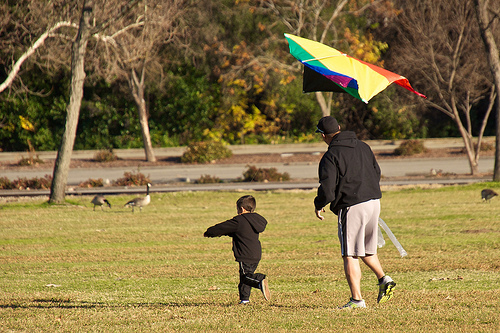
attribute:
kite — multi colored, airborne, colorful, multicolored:
[281, 25, 433, 109]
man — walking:
[315, 113, 404, 309]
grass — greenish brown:
[3, 184, 500, 331]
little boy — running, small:
[201, 186, 278, 306]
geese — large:
[89, 182, 153, 210]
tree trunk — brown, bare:
[45, 4, 110, 205]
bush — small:
[184, 136, 239, 160]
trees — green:
[3, 2, 500, 155]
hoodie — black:
[313, 137, 381, 208]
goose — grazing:
[90, 192, 113, 211]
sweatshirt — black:
[209, 212, 266, 260]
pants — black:
[235, 262, 263, 298]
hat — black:
[314, 118, 343, 132]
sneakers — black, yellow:
[342, 279, 396, 308]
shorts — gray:
[337, 198, 378, 258]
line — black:
[339, 204, 353, 262]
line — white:
[239, 263, 262, 286]